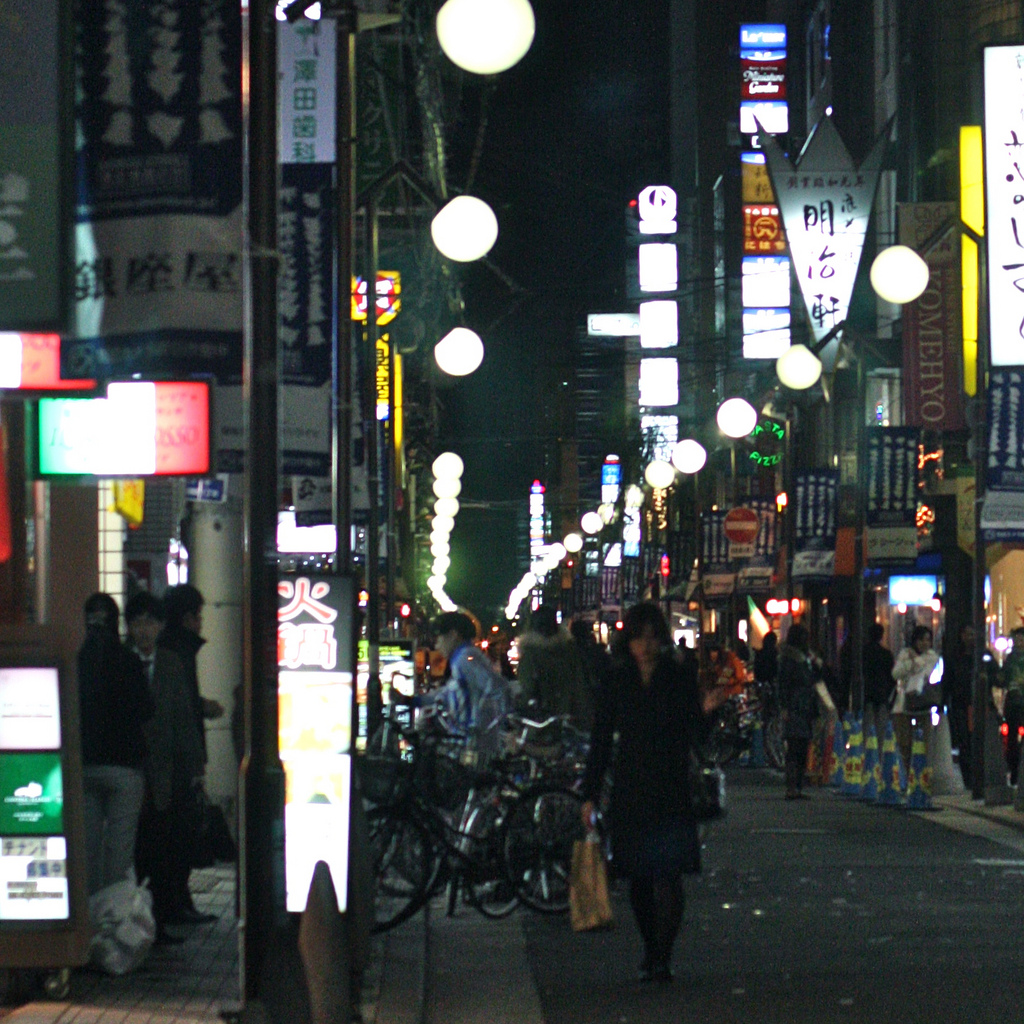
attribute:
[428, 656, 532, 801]
shirt — blue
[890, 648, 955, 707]
shirt — white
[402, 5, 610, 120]
light — white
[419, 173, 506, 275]
light — white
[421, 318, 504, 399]
light — white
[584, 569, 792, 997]
clothes — black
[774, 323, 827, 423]
light — white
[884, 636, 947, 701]
top — white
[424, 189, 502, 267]
streetlight — round, lit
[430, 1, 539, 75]
streetlight — lit, round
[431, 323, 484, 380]
streetlight — round, lit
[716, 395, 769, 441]
streetlight — lit